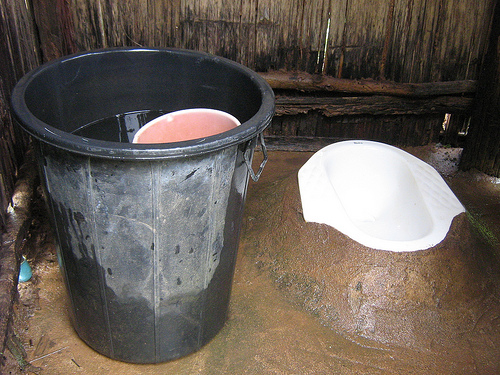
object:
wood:
[254, 0, 476, 152]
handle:
[241, 141, 273, 183]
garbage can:
[8, 42, 279, 368]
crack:
[318, 13, 333, 75]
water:
[80, 101, 156, 146]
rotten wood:
[3, 2, 498, 143]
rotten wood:
[0, 2, 29, 374]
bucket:
[6, 43, 279, 368]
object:
[130, 105, 231, 149]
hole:
[434, 110, 454, 139]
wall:
[220, 2, 487, 142]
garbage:
[3, 35, 282, 365]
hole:
[289, 134, 463, 260]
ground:
[254, 149, 499, 372]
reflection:
[112, 100, 142, 140]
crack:
[440, 113, 456, 143]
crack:
[454, 110, 472, 140]